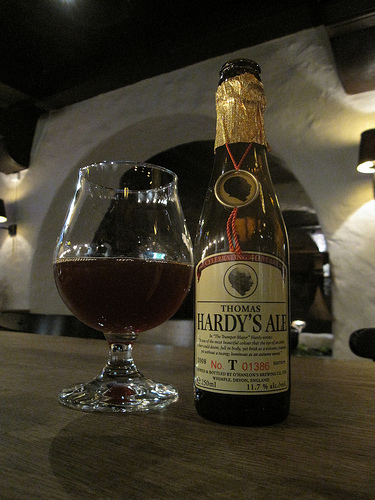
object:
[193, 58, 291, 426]
bottle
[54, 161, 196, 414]
glass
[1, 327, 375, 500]
table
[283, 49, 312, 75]
wall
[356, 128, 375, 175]
lightbulb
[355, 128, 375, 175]
lamp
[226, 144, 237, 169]
string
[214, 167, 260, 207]
medallion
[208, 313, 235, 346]
text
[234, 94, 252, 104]
foil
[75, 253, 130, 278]
wine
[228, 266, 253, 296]
picture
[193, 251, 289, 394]
label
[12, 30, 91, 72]
ceiling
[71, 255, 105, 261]
bubbles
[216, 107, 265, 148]
neck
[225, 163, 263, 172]
liqour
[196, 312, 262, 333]
logo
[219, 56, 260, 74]
bottlecap